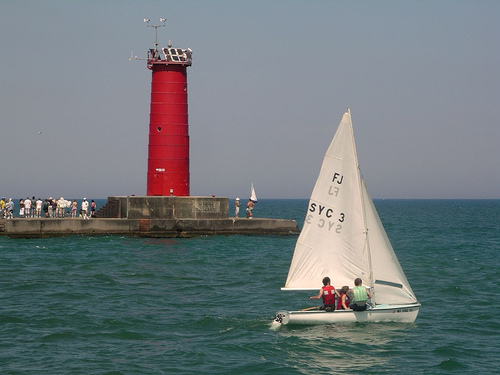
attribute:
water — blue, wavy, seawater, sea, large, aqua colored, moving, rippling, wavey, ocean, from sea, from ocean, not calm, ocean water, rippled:
[1, 199, 499, 374]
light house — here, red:
[147, 49, 190, 197]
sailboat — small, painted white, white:
[270, 109, 422, 330]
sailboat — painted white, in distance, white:
[250, 181, 259, 203]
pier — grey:
[1, 197, 300, 237]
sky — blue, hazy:
[0, 0, 499, 202]